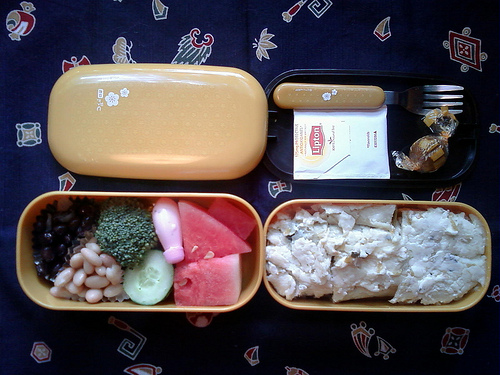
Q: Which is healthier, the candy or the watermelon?
A: The watermelon is healthier than the candy.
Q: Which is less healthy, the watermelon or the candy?
A: The candy is less healthy than the watermelon.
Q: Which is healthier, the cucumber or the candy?
A: The cucumber is healthier than the candy.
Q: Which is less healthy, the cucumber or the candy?
A: The candy is less healthy than the cucumber.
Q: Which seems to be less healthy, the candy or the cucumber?
A: The candy is less healthy than the cucumber.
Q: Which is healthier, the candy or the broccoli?
A: The broccoli is healthier than the candy.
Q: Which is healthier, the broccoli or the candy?
A: The broccoli is healthier than the candy.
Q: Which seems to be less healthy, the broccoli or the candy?
A: The candy is less healthy than the broccoli.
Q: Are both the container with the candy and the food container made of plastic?
A: Yes, both the container and the container are made of plastic.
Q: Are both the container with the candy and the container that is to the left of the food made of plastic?
A: Yes, both the container and the container are made of plastic.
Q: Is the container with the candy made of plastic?
A: Yes, the container is made of plastic.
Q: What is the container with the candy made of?
A: The container is made of plastic.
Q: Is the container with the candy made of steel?
A: No, the container is made of plastic.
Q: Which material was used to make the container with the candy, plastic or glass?
A: The container is made of plastic.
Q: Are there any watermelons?
A: Yes, there is a watermelon.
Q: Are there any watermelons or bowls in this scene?
A: Yes, there is a watermelon.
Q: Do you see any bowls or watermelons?
A: Yes, there is a watermelon.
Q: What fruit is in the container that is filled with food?
A: The fruit is a watermelon.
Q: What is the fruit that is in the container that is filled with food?
A: The fruit is a watermelon.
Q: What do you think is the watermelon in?
A: The watermelon is in the container.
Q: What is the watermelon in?
A: The watermelon is in the container.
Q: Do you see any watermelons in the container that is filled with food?
A: Yes, there is a watermelon in the container.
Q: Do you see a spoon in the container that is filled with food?
A: No, there is a watermelon in the container.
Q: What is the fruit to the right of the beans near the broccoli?
A: The fruit is a watermelon.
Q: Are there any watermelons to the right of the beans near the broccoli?
A: Yes, there is a watermelon to the right of the beans.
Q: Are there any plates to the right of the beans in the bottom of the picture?
A: No, there is a watermelon to the right of the beans.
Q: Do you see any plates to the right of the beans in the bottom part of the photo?
A: No, there is a watermelon to the right of the beans.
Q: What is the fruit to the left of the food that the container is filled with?
A: The fruit is a watermelon.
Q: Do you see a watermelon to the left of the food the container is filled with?
A: Yes, there is a watermelon to the left of the food.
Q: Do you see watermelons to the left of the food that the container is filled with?
A: Yes, there is a watermelon to the left of the food.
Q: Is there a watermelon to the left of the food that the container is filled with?
A: Yes, there is a watermelon to the left of the food.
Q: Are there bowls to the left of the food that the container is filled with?
A: No, there is a watermelon to the left of the food.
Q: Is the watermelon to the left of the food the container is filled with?
A: Yes, the watermelon is to the left of the food.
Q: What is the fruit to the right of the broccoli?
A: The fruit is a watermelon.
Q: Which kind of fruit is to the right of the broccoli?
A: The fruit is a watermelon.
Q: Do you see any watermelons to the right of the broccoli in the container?
A: Yes, there is a watermelon to the right of the broccoli.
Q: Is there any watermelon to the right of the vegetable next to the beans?
A: Yes, there is a watermelon to the right of the broccoli.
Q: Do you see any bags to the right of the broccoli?
A: No, there is a watermelon to the right of the broccoli.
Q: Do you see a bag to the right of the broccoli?
A: No, there is a watermelon to the right of the broccoli.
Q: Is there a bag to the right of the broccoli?
A: No, there is a watermelon to the right of the broccoli.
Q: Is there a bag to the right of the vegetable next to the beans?
A: No, there is a watermelon to the right of the broccoli.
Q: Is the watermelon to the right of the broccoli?
A: Yes, the watermelon is to the right of the broccoli.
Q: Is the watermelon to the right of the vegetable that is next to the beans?
A: Yes, the watermelon is to the right of the broccoli.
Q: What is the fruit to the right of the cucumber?
A: The fruit is a watermelon.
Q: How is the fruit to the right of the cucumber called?
A: The fruit is a watermelon.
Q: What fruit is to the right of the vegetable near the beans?
A: The fruit is a watermelon.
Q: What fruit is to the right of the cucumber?
A: The fruit is a watermelon.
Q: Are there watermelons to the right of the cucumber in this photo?
A: Yes, there is a watermelon to the right of the cucumber.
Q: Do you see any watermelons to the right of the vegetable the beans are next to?
A: Yes, there is a watermelon to the right of the cucumber.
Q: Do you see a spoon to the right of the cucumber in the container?
A: No, there is a watermelon to the right of the cucumber.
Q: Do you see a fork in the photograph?
A: Yes, there is a fork.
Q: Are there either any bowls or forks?
A: Yes, there is a fork.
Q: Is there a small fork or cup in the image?
A: Yes, there is a small fork.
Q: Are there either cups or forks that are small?
A: Yes, the fork is small.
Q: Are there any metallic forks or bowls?
A: Yes, there is a metal fork.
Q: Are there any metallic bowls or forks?
A: Yes, there is a metal fork.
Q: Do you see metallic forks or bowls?
A: Yes, there is a metal fork.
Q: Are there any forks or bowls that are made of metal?
A: Yes, the fork is made of metal.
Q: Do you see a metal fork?
A: Yes, there is a fork that is made of metal.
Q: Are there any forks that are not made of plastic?
A: Yes, there is a fork that is made of metal.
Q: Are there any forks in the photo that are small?
A: Yes, there is a small fork.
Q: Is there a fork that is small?
A: Yes, there is a fork that is small.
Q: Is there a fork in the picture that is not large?
A: Yes, there is a small fork.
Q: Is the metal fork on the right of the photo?
A: Yes, the fork is on the right of the image.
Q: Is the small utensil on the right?
A: Yes, the fork is on the right of the image.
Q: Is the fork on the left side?
A: No, the fork is on the right of the image.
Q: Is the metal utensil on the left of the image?
A: No, the fork is on the right of the image.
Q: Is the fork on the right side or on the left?
A: The fork is on the right of the image.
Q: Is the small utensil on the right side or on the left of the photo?
A: The fork is on the right of the image.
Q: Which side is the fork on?
A: The fork is on the right of the image.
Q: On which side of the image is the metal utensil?
A: The fork is on the right of the image.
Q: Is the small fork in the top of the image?
A: Yes, the fork is in the top of the image.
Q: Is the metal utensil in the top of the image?
A: Yes, the fork is in the top of the image.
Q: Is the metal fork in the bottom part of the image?
A: No, the fork is in the top of the image.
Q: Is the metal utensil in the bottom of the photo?
A: No, the fork is in the top of the image.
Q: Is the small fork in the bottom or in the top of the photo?
A: The fork is in the top of the image.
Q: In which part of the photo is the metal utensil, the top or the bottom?
A: The fork is in the top of the image.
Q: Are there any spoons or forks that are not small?
A: No, there is a fork but it is small.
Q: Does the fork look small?
A: Yes, the fork is small.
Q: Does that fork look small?
A: Yes, the fork is small.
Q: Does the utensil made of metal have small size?
A: Yes, the fork is small.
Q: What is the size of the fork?
A: The fork is small.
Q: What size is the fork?
A: The fork is small.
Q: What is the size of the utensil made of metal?
A: The fork is small.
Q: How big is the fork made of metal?
A: The fork is small.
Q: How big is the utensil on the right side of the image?
A: The fork is small.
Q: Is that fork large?
A: No, the fork is small.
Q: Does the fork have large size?
A: No, the fork is small.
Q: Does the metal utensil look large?
A: No, the fork is small.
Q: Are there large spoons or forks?
A: No, there is a fork but it is small.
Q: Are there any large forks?
A: No, there is a fork but it is small.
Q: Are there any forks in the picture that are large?
A: No, there is a fork but it is small.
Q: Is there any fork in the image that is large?
A: No, there is a fork but it is small.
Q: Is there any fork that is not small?
A: No, there is a fork but it is small.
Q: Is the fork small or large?
A: The fork is small.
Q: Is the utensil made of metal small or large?
A: The fork is small.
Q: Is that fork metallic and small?
A: Yes, the fork is metallic and small.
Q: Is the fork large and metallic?
A: No, the fork is metallic but small.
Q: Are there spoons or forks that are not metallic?
A: No, there is a fork but it is metallic.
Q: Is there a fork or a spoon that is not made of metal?
A: No, there is a fork but it is made of metal.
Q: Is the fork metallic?
A: Yes, the fork is metallic.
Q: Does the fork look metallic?
A: Yes, the fork is metallic.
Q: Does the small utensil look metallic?
A: Yes, the fork is metallic.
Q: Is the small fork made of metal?
A: Yes, the fork is made of metal.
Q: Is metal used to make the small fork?
A: Yes, the fork is made of metal.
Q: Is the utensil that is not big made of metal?
A: Yes, the fork is made of metal.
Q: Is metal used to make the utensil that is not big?
A: Yes, the fork is made of metal.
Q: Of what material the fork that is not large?
A: The fork is made of metal.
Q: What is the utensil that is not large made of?
A: The fork is made of metal.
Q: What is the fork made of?
A: The fork is made of metal.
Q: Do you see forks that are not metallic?
A: No, there is a fork but it is metallic.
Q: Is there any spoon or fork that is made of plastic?
A: No, there is a fork but it is made of metal.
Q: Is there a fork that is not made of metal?
A: No, there is a fork but it is made of metal.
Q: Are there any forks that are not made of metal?
A: No, there is a fork but it is made of metal.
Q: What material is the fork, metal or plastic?
A: The fork is made of metal.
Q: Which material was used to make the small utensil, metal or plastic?
A: The fork is made of metal.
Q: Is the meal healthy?
A: Yes, the meal is healthy.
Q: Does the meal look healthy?
A: Yes, the meal is healthy.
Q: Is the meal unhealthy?
A: No, the meal is healthy.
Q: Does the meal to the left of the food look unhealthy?
A: No, the meal is healthy.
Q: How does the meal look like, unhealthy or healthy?
A: The meal is healthy.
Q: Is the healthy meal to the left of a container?
A: Yes, the meal is to the left of a container.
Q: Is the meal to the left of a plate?
A: No, the meal is to the left of a container.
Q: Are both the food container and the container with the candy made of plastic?
A: Yes, both the container and the container are made of plastic.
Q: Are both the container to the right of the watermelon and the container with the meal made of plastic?
A: Yes, both the container and the container are made of plastic.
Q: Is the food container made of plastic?
A: Yes, the container is made of plastic.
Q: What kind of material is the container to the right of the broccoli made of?
A: The container is made of plastic.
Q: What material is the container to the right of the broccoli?
A: The container is made of plastic.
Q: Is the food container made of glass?
A: No, the container is made of plastic.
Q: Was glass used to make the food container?
A: No, the container is made of plastic.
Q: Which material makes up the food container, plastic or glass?
A: The container is made of plastic.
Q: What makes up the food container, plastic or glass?
A: The container is made of plastic.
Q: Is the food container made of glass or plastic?
A: The container is made of plastic.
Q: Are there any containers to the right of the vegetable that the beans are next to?
A: Yes, there is a container to the right of the cucumber.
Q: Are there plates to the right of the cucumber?
A: No, there is a container to the right of the cucumber.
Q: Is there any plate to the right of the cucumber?
A: No, there is a container to the right of the cucumber.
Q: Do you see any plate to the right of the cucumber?
A: No, there is a container to the right of the cucumber.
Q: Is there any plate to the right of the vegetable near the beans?
A: No, there is a container to the right of the cucumber.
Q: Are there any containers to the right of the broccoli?
A: Yes, there is a container to the right of the broccoli.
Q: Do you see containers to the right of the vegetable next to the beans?
A: Yes, there is a container to the right of the broccoli.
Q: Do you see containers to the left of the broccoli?
A: No, the container is to the right of the broccoli.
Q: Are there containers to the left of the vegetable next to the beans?
A: No, the container is to the right of the broccoli.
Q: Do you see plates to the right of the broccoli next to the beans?
A: No, there is a container to the right of the broccoli.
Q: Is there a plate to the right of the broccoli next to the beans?
A: No, there is a container to the right of the broccoli.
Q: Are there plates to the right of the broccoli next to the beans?
A: No, there is a container to the right of the broccoli.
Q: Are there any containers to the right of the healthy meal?
A: Yes, there is a container to the right of the meal.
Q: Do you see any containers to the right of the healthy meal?
A: Yes, there is a container to the right of the meal.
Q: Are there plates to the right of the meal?
A: No, there is a container to the right of the meal.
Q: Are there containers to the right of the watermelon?
A: Yes, there is a container to the right of the watermelon.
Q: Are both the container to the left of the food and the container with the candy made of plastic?
A: Yes, both the container and the container are made of plastic.